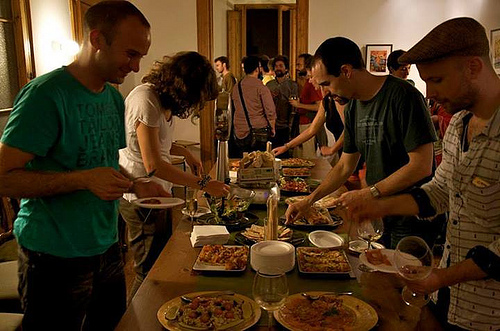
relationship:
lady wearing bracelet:
[145, 54, 217, 212] [196, 173, 209, 190]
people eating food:
[1, 0, 152, 329] [155, 292, 260, 330]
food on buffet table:
[155, 292, 260, 330] [111, 128, 431, 330]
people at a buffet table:
[398, 19, 499, 331] [111, 128, 431, 330]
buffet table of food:
[111, 128, 431, 330] [296, 244, 349, 277]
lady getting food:
[107, 36, 227, 298] [358, 235, 419, 276]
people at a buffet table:
[1, 0, 152, 329] [132, 142, 420, 330]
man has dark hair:
[312, 36, 432, 188] [312, 36, 365, 74]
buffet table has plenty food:
[132, 142, 420, 330] [296, 244, 349, 277]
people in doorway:
[229, 55, 278, 145] [198, 0, 308, 148]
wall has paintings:
[308, 3, 423, 36] [364, 41, 392, 78]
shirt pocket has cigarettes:
[467, 171, 498, 215] [471, 173, 492, 191]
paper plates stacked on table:
[249, 240, 295, 274] [132, 142, 420, 330]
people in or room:
[214, 53, 235, 113] [212, 2, 296, 60]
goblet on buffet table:
[252, 267, 290, 330] [132, 142, 420, 330]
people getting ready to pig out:
[398, 19, 499, 331] [132, 142, 420, 330]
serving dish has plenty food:
[296, 244, 349, 277] [155, 292, 260, 330]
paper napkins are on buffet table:
[190, 222, 229, 249] [132, 142, 420, 330]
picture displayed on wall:
[364, 41, 392, 78] [308, 3, 423, 36]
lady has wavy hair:
[107, 36, 227, 298] [142, 51, 221, 118]